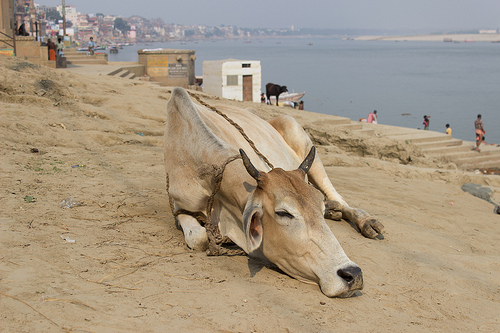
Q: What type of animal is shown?
A: Cow.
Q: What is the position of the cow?
A: Laying.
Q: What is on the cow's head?
A: Horns.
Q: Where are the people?
A: Next to the water.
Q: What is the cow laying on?
A: Dirt.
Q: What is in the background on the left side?
A: Buildings.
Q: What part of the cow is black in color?
A: Nose.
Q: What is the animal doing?
A: Laying down.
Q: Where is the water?
A: In the back.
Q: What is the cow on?
A: The beach.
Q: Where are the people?
A: In the back.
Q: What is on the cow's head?
A: Horns.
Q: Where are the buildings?
A: Behind the cow.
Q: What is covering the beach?
A: Sand.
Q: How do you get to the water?
A: Take the steps.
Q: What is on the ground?
A: A cow.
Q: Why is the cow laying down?
A: To rest.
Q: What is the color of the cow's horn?
A: Black.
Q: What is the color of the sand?
A: Light brown.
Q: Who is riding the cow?
A: No one.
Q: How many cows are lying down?
A: One.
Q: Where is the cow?
A: On the ground.